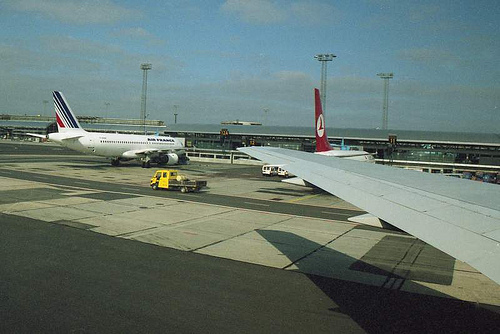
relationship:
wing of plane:
[236, 139, 498, 307] [234, 142, 499, 284]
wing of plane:
[309, 87, 334, 150] [294, 85, 375, 183]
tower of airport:
[309, 53, 338, 121] [0, 115, 494, 324]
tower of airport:
[376, 72, 401, 131] [0, 115, 494, 324]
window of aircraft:
[98, 137, 102, 143] [19, 82, 195, 167]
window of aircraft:
[104, 135, 107, 143] [19, 82, 195, 167]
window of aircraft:
[116, 139, 121, 144] [19, 82, 195, 167]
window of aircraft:
[137, 140, 142, 145] [19, 82, 195, 167]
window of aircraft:
[156, 140, 162, 144] [19, 82, 195, 167]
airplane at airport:
[313, 87, 375, 161] [0, 0, 499, 332]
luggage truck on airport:
[152, 168, 207, 192] [0, 0, 499, 332]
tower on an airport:
[371, 65, 401, 144] [0, 115, 494, 324]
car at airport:
[277, 167, 290, 177] [0, 115, 494, 324]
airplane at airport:
[311, 87, 376, 163] [0, 115, 494, 324]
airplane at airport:
[26, 90, 191, 169] [0, 115, 494, 324]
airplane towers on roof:
[140, 64, 154, 126] [63, 124, 497, 155]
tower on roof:
[309, 53, 338, 121] [152, 123, 498, 154]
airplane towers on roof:
[123, 45, 398, 127] [11, 112, 498, 170]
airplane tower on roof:
[36, 93, 51, 120] [5, 100, 495, 164]